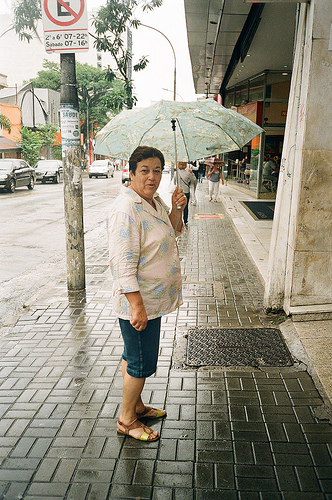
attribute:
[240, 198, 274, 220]
mat — black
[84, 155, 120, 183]
van — white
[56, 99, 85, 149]
flyer — green, white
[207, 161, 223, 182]
shirt — blue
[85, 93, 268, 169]
umbrella — unfolded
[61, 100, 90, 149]
sign — red, black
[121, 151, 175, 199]
face — person's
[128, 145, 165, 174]
hair — dark brown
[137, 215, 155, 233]
flower — white, blue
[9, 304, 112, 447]
bricks — brown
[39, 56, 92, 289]
pole — wooden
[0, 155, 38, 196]
car — black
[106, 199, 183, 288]
shirt — pink